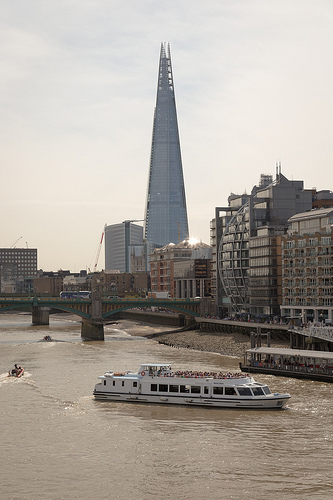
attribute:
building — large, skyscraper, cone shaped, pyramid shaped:
[146, 37, 191, 265]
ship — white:
[91, 358, 299, 416]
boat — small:
[43, 332, 57, 346]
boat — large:
[242, 342, 331, 376]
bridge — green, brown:
[2, 288, 208, 340]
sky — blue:
[12, 16, 130, 214]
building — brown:
[93, 270, 155, 294]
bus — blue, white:
[58, 286, 99, 300]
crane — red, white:
[93, 226, 107, 271]